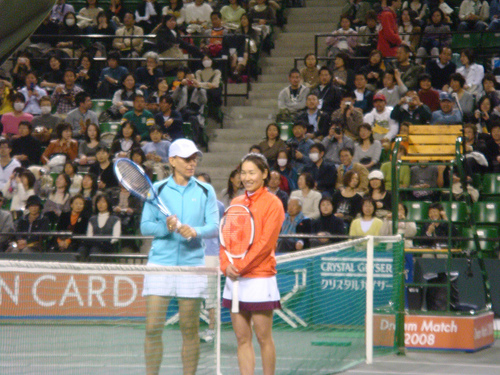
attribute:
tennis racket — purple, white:
[179, 200, 291, 335]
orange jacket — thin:
[218, 188, 285, 278]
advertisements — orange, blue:
[10, 229, 432, 344]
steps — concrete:
[194, 0, 347, 198]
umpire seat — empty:
[395, 125, 472, 159]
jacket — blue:
[136, 173, 223, 265]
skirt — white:
[221, 275, 286, 311]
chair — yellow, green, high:
[349, 116, 496, 324]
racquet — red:
[217, 202, 255, 314]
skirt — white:
[219, 257, 267, 312]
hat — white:
[169, 137, 205, 158]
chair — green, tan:
[392, 121, 468, 164]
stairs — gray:
[253, 28, 278, 164]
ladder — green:
[398, 169, 460, 317]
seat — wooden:
[391, 119, 468, 246]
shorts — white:
[140, 262, 207, 298]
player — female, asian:
[219, 152, 284, 373]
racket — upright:
[216, 202, 256, 313]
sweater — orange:
[219, 189, 266, 256]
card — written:
[31, 275, 138, 307]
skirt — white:
[217, 262, 329, 331]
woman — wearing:
[216, 150, 286, 374]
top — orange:
[219, 188, 289, 273]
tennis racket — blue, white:
[110, 154, 180, 231]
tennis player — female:
[122, 122, 207, 373]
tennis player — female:
[215, 144, 281, 372]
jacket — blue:
[139, 172, 219, 267]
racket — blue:
[110, 153, 192, 239]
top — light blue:
[161, 189, 195, 236]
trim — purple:
[249, 303, 283, 313]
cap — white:
[172, 144, 194, 160]